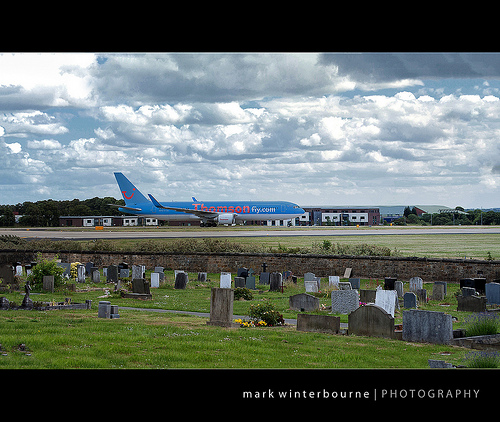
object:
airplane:
[104, 169, 307, 231]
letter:
[190, 201, 201, 214]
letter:
[200, 201, 209, 216]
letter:
[215, 204, 228, 214]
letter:
[235, 206, 244, 214]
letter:
[268, 206, 277, 214]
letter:
[259, 206, 267, 215]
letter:
[253, 206, 262, 215]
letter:
[250, 204, 256, 216]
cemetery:
[0, 249, 499, 368]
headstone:
[400, 308, 455, 349]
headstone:
[346, 303, 399, 339]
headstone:
[295, 311, 344, 337]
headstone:
[204, 284, 239, 328]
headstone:
[326, 287, 361, 316]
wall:
[0, 248, 499, 289]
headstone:
[372, 287, 399, 320]